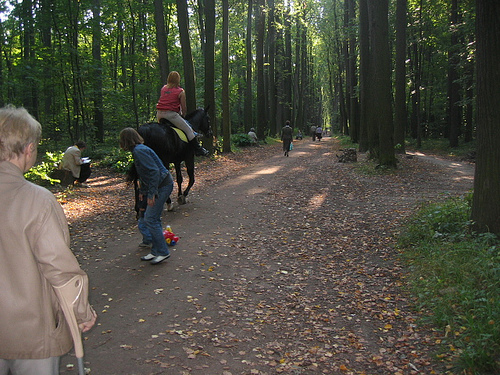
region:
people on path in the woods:
[7, 74, 220, 364]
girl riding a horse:
[146, 68, 226, 208]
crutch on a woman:
[35, 275, 115, 373]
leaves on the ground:
[256, 311, 396, 365]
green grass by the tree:
[426, 205, 491, 341]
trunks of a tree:
[349, 82, 409, 178]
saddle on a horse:
[158, 124, 193, 145]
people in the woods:
[275, 111, 334, 156]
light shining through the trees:
[302, 4, 346, 35]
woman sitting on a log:
[54, 136, 96, 192]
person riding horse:
[126, 61, 211, 196]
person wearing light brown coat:
[2, 108, 108, 374]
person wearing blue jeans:
[113, 131, 179, 275]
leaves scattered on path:
[98, 116, 408, 373]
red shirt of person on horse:
[153, 82, 185, 114]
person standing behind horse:
[113, 126, 177, 262]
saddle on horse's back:
[163, 115, 198, 150]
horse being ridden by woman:
[118, 98, 216, 204]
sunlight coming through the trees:
[23, 8, 332, 72]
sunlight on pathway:
[63, 118, 335, 218]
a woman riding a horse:
[126, 57, 218, 157]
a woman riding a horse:
[91, 56, 226, 198]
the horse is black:
[138, 105, 229, 175]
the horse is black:
[105, 63, 217, 205]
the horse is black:
[115, 50, 270, 257]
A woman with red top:
[155, 79, 190, 112]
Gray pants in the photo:
[149, 109, 198, 141]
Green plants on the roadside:
[412, 232, 487, 340]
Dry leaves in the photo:
[277, 249, 393, 359]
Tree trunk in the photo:
[370, 78, 394, 164]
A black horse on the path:
[135, 97, 210, 216]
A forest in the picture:
[320, 44, 491, 166]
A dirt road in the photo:
[168, 202, 345, 334]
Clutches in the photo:
[46, 259, 105, 374]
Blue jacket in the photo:
[127, 147, 168, 187]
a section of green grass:
[407, 190, 498, 363]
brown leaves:
[166, 317, 233, 357]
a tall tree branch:
[174, 0, 211, 155]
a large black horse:
[127, 104, 217, 220]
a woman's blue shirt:
[130, 143, 171, 193]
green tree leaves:
[78, 28, 91, 61]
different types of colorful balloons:
[156, 221, 181, 249]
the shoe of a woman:
[147, 246, 173, 264]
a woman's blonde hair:
[161, 68, 186, 90]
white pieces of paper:
[81, 155, 94, 165]